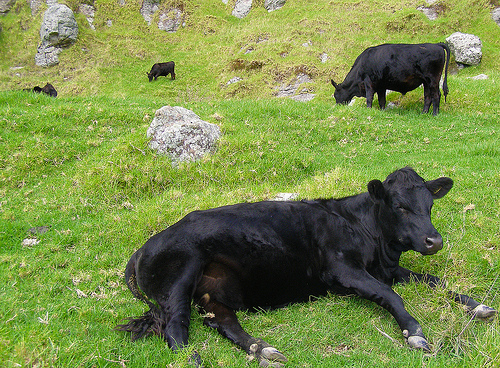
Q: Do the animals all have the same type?
A: Yes, all the animals are cows.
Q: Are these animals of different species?
A: No, all the animals are cows.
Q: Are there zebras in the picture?
A: No, there are no zebras.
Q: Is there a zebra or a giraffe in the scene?
A: No, there are no zebras or giraffes.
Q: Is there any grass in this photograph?
A: Yes, there is grass.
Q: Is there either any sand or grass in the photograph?
A: Yes, there is grass.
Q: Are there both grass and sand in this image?
A: No, there is grass but no sand.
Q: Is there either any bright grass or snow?
A: Yes, there is bright grass.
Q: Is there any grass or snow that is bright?
A: Yes, the grass is bright.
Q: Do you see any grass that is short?
A: Yes, there is short grass.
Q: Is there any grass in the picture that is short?
A: Yes, there is grass that is short.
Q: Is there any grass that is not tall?
A: Yes, there is short grass.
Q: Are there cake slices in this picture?
A: No, there are no cake slices.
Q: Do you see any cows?
A: Yes, there are cows.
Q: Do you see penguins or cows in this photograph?
A: Yes, there are cows.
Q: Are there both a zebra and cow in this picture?
A: No, there are cows but no zebras.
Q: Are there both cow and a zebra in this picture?
A: No, there are cows but no zebras.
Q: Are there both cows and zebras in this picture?
A: No, there are cows but no zebras.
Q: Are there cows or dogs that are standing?
A: Yes, the cows are standing.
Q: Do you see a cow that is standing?
A: Yes, there are cows that are standing.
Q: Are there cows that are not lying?
A: Yes, there are cows that are standing.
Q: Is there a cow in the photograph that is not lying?
A: Yes, there are cows that are standing.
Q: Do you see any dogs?
A: No, there are no dogs.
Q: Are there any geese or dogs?
A: No, there are no dogs or geese.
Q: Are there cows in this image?
A: Yes, there is a cow.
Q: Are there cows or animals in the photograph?
A: Yes, there is a cow.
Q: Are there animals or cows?
A: Yes, there is a cow.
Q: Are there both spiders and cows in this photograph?
A: No, there is a cow but no spiders.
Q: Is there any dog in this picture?
A: No, there are no dogs.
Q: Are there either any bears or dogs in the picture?
A: No, there are no dogs or bears.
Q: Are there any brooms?
A: No, there are no brooms.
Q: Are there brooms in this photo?
A: No, there are no brooms.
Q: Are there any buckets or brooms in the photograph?
A: No, there are no brooms or buckets.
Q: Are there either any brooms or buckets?
A: No, there are no brooms or buckets.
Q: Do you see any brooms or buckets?
A: No, there are no brooms or buckets.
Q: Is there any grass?
A: Yes, there is grass.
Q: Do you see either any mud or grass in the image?
A: Yes, there is grass.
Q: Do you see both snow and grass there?
A: No, there is grass but no snow.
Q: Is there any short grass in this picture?
A: Yes, there is short grass.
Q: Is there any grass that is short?
A: Yes, there is grass that is short.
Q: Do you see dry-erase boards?
A: No, there are no dry-erase boards.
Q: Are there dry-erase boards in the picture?
A: No, there are no dry-erase boards.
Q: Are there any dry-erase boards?
A: No, there are no dry-erase boards.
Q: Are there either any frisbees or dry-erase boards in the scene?
A: No, there are no dry-erase boards or frisbees.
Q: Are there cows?
A: Yes, there are cows.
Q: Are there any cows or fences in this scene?
A: Yes, there are cows.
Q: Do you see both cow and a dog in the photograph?
A: No, there are cows but no dogs.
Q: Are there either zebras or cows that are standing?
A: Yes, the cows are standing.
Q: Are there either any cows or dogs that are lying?
A: Yes, the cows are lying.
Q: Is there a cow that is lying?
A: Yes, there are cows that are lying.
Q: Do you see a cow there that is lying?
A: Yes, there are cows that are lying.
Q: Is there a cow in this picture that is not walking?
A: Yes, there are cows that are lying.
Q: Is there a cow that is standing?
A: Yes, there are cows that are standing.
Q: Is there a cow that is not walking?
A: Yes, there are cows that are standing.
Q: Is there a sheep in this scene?
A: No, there is no sheep.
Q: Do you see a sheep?
A: No, there is no sheep.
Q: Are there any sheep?
A: No, there are no sheep.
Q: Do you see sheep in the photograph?
A: No, there are no sheep.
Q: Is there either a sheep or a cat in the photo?
A: No, there are no sheep or cats.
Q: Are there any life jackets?
A: No, there are no life jackets.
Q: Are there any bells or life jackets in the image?
A: No, there are no life jackets or bells.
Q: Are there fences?
A: No, there are no fences.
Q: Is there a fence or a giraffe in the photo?
A: No, there are no fences or giraffes.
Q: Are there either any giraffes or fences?
A: No, there are no fences or giraffes.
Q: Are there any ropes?
A: No, there are no ropes.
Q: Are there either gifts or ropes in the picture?
A: No, there are no ropes or gifts.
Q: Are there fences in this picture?
A: No, there are no fences.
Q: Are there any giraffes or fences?
A: No, there are no fences or giraffes.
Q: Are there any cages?
A: No, there are no cages.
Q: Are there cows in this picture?
A: Yes, there are cows.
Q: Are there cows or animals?
A: Yes, there are cows.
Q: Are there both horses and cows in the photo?
A: No, there are cows but no horses.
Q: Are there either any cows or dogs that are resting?
A: Yes, the cows are resting.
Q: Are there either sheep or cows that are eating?
A: Yes, the cows are eating.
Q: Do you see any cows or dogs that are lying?
A: Yes, the cows are lying.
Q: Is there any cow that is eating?
A: Yes, there are cows that are eating.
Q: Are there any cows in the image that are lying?
A: Yes, there are cows that are lying.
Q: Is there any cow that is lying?
A: Yes, there are cows that are lying.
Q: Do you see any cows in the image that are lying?
A: Yes, there are cows that are lying.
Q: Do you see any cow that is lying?
A: Yes, there are cows that are lying.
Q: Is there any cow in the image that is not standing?
A: Yes, there are cows that are lying.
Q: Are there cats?
A: No, there are no cats.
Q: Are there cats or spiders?
A: No, there are no cats or spiders.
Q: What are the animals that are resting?
A: The animals are cows.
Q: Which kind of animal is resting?
A: The animal is cows.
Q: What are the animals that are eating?
A: The animals are cows.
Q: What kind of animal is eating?
A: The animal is cows.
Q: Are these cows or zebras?
A: These are cows.